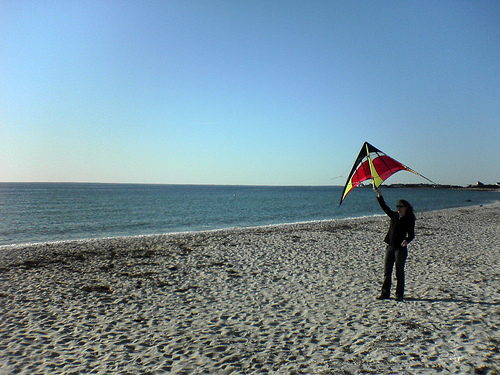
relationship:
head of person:
[391, 194, 419, 220] [372, 150, 425, 301]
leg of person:
[378, 247, 411, 290] [372, 150, 425, 301]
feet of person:
[361, 290, 418, 311] [372, 150, 425, 301]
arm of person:
[357, 190, 402, 215] [372, 150, 425, 301]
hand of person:
[367, 185, 385, 196] [372, 150, 425, 301]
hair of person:
[398, 202, 420, 221] [372, 150, 425, 301]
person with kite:
[372, 189, 415, 301] [326, 147, 400, 187]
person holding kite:
[372, 189, 415, 301] [326, 147, 400, 187]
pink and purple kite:
[337, 133, 404, 185] [326, 147, 400, 187]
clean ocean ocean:
[79, 181, 168, 207] [0, 183, 499, 262]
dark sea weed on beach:
[74, 239, 159, 275] [224, 305, 340, 371]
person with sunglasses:
[372, 189, 415, 301] [391, 199, 411, 217]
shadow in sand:
[439, 293, 486, 314] [224, 300, 423, 347]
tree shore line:
[434, 176, 460, 189] [421, 186, 453, 197]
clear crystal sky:
[105, 77, 235, 153] [141, 84, 221, 132]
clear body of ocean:
[105, 77, 235, 153] [0, 183, 499, 262]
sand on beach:
[224, 300, 423, 347] [224, 305, 340, 371]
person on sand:
[372, 189, 415, 301] [224, 300, 423, 347]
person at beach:
[372, 189, 415, 301] [224, 305, 340, 371]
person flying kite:
[372, 189, 415, 301] [326, 147, 400, 187]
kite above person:
[326, 147, 400, 187] [372, 189, 415, 301]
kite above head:
[326, 147, 400, 187] [391, 194, 419, 220]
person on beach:
[372, 189, 415, 301] [224, 305, 340, 371]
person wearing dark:
[372, 189, 415, 301] [385, 222, 420, 244]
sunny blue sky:
[114, 43, 248, 160] [141, 84, 221, 132]